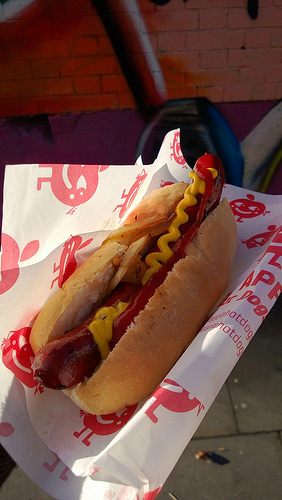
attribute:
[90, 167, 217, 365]
mustard — yellow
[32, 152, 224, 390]
hot dog — pink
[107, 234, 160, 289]
onions — grilled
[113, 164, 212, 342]
ketchup — red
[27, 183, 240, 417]
roll — toasted, tan, hardy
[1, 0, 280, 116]
wall — brick, graffitied, painted, red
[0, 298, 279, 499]
floor — grey, tiled, crumby, trashy, bricked, concrete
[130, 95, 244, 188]
chair — black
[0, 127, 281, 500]
paper — red, white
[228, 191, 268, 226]
logo — red apple, red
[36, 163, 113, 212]
logo — red